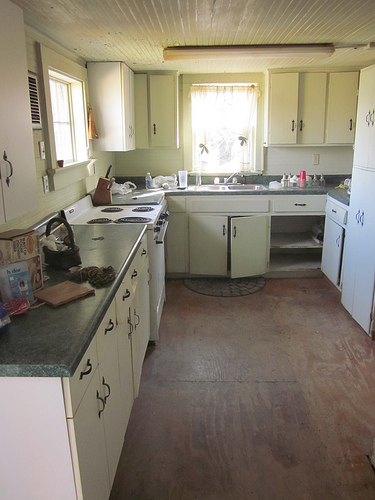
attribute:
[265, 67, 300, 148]
cupboard — white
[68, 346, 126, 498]
cabinet — metal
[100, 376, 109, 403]
handle — black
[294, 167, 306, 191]
cups — red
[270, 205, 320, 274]
cabinet — open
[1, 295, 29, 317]
can — red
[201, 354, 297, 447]
wood floor — wooden, brown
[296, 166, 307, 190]
can — red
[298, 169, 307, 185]
can — red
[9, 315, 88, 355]
counter — green, formica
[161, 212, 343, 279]
cabinet — open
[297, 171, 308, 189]
plastic cups — red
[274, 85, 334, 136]
cabinet — white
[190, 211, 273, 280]
cabinet — open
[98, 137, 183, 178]
wall — white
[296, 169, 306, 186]
cups — stacked, red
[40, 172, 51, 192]
electrical outlet — white